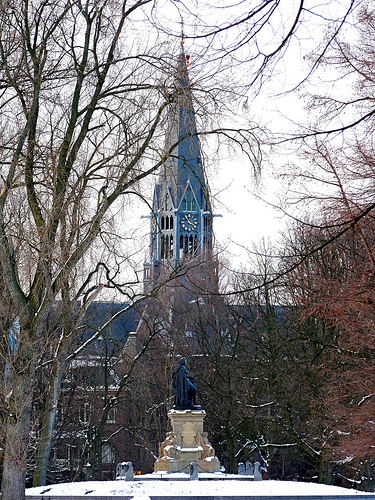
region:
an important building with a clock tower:
[8, 15, 369, 494]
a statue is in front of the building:
[28, 336, 373, 495]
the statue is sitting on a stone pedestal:
[155, 353, 223, 473]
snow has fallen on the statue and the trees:
[12, 195, 374, 491]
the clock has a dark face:
[177, 211, 201, 235]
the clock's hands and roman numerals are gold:
[179, 211, 199, 235]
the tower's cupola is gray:
[151, 51, 209, 211]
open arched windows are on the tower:
[150, 211, 221, 262]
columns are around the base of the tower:
[141, 260, 220, 283]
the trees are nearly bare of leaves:
[6, 33, 369, 476]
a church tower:
[103, 29, 247, 374]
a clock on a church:
[161, 200, 214, 242]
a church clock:
[166, 202, 216, 254]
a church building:
[9, 118, 374, 490]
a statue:
[139, 330, 233, 478]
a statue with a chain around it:
[99, 333, 271, 496]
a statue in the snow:
[78, 344, 264, 495]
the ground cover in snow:
[24, 428, 235, 499]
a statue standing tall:
[114, 321, 286, 488]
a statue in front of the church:
[80, 269, 316, 499]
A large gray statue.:
[156, 349, 209, 434]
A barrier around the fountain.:
[107, 451, 262, 483]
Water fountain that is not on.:
[141, 405, 209, 475]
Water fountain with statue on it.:
[110, 345, 275, 482]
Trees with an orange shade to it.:
[305, 318, 373, 470]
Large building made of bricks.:
[34, 320, 151, 476]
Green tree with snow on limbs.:
[229, 327, 295, 448]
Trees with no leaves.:
[6, 330, 87, 489]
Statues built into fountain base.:
[125, 403, 223, 473]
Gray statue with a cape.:
[160, 346, 208, 417]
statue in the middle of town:
[162, 357, 230, 468]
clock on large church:
[177, 208, 204, 235]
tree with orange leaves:
[294, 270, 370, 461]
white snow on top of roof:
[226, 480, 286, 493]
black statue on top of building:
[167, 356, 205, 412]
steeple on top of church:
[172, 15, 197, 64]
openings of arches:
[154, 212, 175, 255]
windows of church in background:
[72, 400, 117, 433]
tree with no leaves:
[7, 186, 152, 351]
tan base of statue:
[160, 402, 220, 477]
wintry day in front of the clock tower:
[63, 121, 334, 487]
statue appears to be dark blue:
[161, 355, 209, 411]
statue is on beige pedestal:
[143, 395, 234, 476]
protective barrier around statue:
[105, 451, 274, 484]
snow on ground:
[57, 377, 330, 494]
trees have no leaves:
[23, 11, 145, 240]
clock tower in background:
[155, 38, 221, 317]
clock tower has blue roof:
[148, 58, 221, 208]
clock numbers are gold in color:
[176, 207, 202, 232]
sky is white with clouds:
[217, 64, 295, 235]